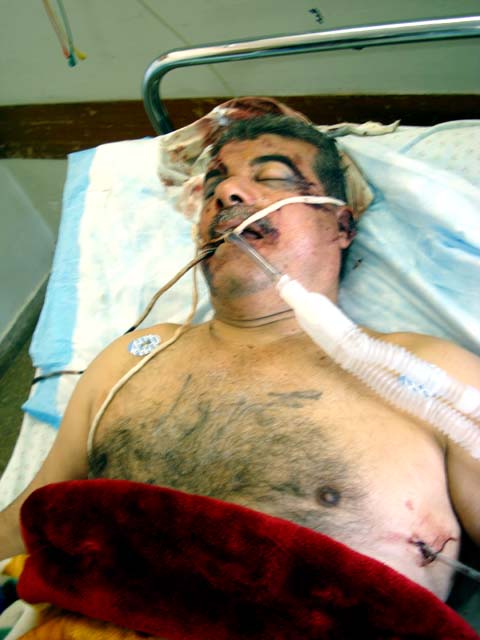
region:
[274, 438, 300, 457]
hair on the chest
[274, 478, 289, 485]
hair on the chest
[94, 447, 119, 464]
hair on the chest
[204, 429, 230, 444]
hair on the chest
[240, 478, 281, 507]
hair on the chest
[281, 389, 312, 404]
hair on the chest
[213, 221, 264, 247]
mouth is hanging open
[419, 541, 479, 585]
thin and clear tube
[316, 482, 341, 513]
dark nipple on the chest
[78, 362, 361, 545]
dark brown hair on the chest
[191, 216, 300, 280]
tube is hanging out of the mouth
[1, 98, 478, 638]
man is laying down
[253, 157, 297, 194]
eye is closed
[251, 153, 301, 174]
dark eyebrow is above the eye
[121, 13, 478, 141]
shiny silver railing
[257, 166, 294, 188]
eye is closed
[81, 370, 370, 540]
dark hair is on the chest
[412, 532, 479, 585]
thin, clear tube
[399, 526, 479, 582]
tube is sticking in the body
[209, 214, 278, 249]
mouth is slightly open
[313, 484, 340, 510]
dark nipple is on the chest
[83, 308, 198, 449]
wire is laying over the man's chest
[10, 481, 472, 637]
The red cover over the man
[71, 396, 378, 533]
the hairy chest of the person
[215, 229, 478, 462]
The clear plastic tube from the man's mouth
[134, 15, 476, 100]
The steel metal bar headboard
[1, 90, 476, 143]
The wood portion on the wall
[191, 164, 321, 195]
The closed eyes of the man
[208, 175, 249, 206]
The nose of the man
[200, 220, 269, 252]
The mouth of the man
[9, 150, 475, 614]
The man lying on the bed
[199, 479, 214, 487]
hair on the chest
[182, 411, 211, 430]
hair on the chest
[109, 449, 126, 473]
hair on the chest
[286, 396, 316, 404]
hair on the chest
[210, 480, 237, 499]
hair on the chest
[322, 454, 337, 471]
hair on the chest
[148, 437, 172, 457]
hair on the chest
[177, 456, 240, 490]
hair on the chest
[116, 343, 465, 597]
The chest of the man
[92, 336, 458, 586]
A chest of the man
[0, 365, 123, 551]
The left hand of the man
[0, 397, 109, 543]
A left hand of the man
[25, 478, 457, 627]
The maroon blanket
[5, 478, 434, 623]
A maroon blanket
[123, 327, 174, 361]
A blue and white sticker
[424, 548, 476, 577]
needle in a man's side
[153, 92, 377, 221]
bloody cloth above his head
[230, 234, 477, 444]
tube with white bristles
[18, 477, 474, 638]
red soft wrap around his middle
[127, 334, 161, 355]
white round sticker on his shoulder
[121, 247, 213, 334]
tube coming out of his mouth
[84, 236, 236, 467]
tube coming out of his mouth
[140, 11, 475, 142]
silver metal bar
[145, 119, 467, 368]
a man in the bed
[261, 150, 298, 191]
eyebrow on the man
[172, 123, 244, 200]
eyebrow on the man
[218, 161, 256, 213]
nose on the man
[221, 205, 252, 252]
mouth on the man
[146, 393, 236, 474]
hair ont he chest